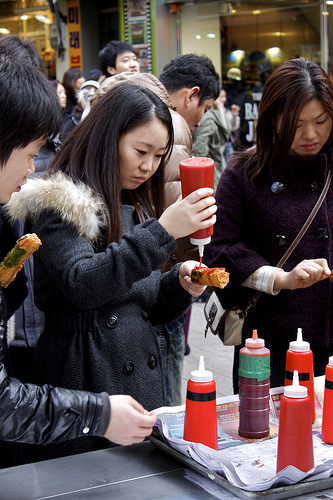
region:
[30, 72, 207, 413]
Woman wearing a gray coat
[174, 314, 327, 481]
Sauces for food on newspaper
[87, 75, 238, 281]
Woman putting sauce on her food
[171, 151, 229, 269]
Sauce is in bright red bottle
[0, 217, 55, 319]
Someone holding fried food on a stick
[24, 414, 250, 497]
The table is gray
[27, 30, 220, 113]
People are in the background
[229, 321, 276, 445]
Bottle has green tape around it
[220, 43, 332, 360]
Woman is wearing a purple coat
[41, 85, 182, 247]
Woman has light colored fur on her coat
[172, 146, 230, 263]
Woman is using ketchup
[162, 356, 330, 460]
Many bottles of sauce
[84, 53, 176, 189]
Woman has dark hair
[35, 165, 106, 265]
Fur on jacket collar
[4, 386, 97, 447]
Man wearing black jacket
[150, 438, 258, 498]
Metal tray underneath papers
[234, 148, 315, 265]
Woman wearing purple jacket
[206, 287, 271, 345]
Tan purse around woman's shoulder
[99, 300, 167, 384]
Large buttons on woman's coat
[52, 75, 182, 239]
the girl is asian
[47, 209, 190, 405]
the coat is gray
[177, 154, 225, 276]
the ketchup is red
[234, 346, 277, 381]
the top is green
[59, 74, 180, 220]
her hair is black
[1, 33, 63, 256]
the boy is asian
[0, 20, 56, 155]
the boy has black hair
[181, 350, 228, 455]
the bottles are red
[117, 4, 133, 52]
part of the wall is green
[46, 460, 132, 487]
the counter is gray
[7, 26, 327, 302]
people eating corn dogs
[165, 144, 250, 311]
woman using ketchup style plastic bottle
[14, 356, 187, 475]
man reaching for sauce in plastic bottle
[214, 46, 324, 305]
woman in purple coat looking down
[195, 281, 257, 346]
small white shoulder bag purse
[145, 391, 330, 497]
red plastic bottles on tray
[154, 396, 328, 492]
red bottles on newspaper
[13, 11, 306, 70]
busy street and storefronts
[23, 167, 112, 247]
fur collar on woman's coat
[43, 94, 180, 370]
this is a woman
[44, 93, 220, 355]
the woman is pasting the hotdog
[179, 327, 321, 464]
the bottles of tomato sauce are on the table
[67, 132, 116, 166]
the woman has long hair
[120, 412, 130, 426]
the man is white in color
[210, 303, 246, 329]
the woman is carrying a hand bag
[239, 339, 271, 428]
the can is red in color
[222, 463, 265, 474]
the cans are placed on newspaper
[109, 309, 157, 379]
the womans trench coat is buttoned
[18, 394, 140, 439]
the mans hand is raised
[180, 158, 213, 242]
a plastic ketchup bottle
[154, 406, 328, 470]
newspapers on a tray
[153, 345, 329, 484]
bottles on a tray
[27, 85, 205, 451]
a girl in a grey jacket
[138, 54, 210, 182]
a man in a brown coat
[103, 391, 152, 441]
the hand of a person